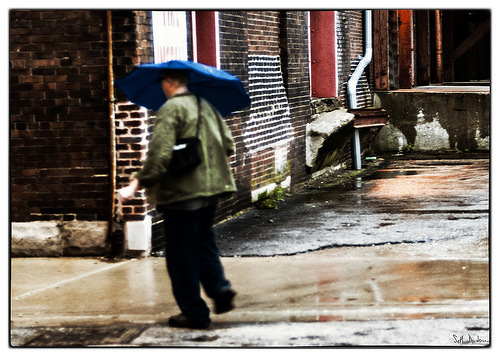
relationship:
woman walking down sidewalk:
[121, 47, 262, 311] [236, 229, 366, 313]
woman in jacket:
[127, 65, 240, 325] [125, 92, 233, 194]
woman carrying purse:
[127, 65, 240, 325] [120, 139, 239, 202]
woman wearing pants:
[127, 65, 240, 325] [148, 179, 231, 317]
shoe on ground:
[140, 274, 283, 337] [34, 213, 444, 333]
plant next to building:
[242, 118, 386, 244] [49, 34, 440, 266]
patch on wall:
[404, 86, 462, 188] [141, 34, 428, 270]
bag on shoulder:
[105, 104, 224, 276] [132, 90, 260, 140]